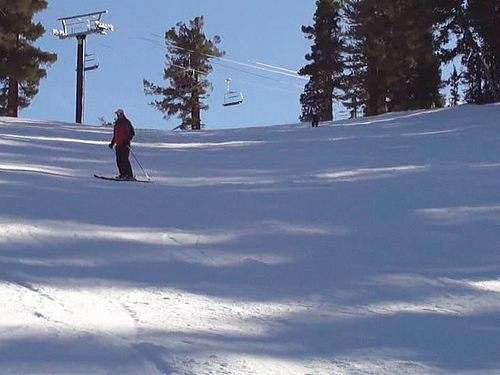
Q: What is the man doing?
A: Standing.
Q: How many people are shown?
A: Two.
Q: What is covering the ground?
A: Snow.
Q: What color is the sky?
A: Blue.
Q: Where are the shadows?
A: On the snow.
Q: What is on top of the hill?
A: Trees.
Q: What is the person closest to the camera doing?
A: Skiing.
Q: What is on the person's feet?
A: Skis.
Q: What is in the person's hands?
A: Ski poles.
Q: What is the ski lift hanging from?
A: Wires.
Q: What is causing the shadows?
A: Sun.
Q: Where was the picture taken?
A: On a ski slope.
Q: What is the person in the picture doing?
A: Skiing.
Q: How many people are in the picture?
A: 2.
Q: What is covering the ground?
A: Snow.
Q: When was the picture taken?
A: Winter.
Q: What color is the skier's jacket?
A: Red.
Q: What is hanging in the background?
A: Chairlift.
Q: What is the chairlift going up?
A: A mountain.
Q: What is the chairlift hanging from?
A: Cables.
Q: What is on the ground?
A: Snow.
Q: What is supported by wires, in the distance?
A: A ski-lift chair.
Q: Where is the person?
A: On the ski slope.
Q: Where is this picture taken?
A: The ski slope.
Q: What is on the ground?
A: Snow.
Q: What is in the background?
A: Trees.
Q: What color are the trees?
A: Green.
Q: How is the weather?
A: Clear.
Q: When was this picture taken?
A: Day Time.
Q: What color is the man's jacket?
A: Red.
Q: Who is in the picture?
A: A man.